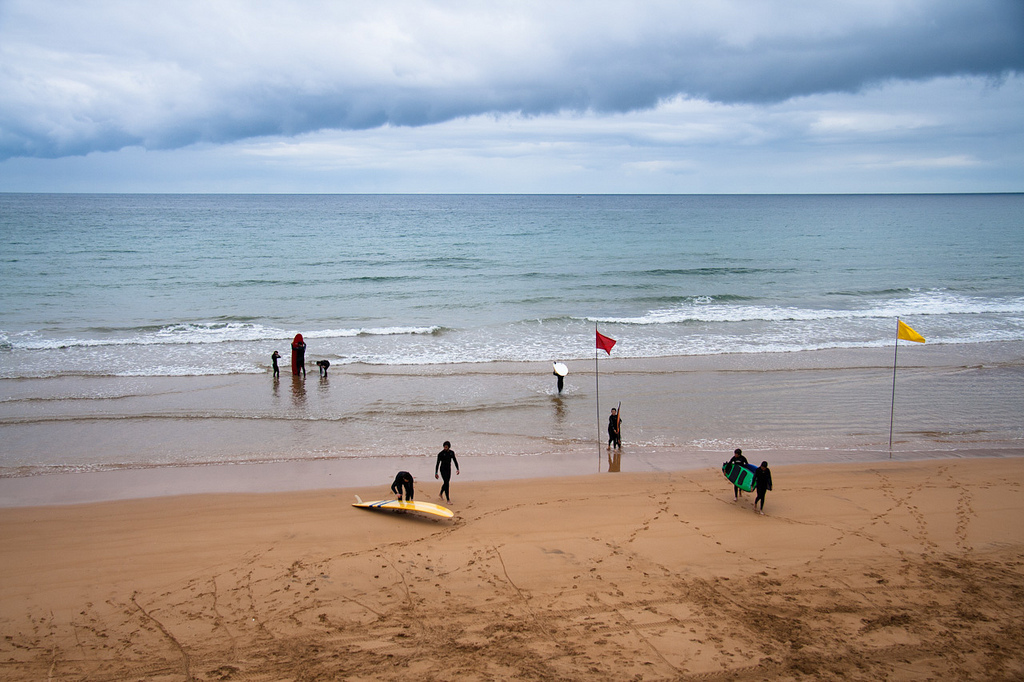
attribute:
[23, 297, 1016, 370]
waves — rushing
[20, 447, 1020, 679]
sand — smooth, brown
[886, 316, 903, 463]
pole — small, thin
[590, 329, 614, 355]
flag — red, small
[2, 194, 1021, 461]
water — large